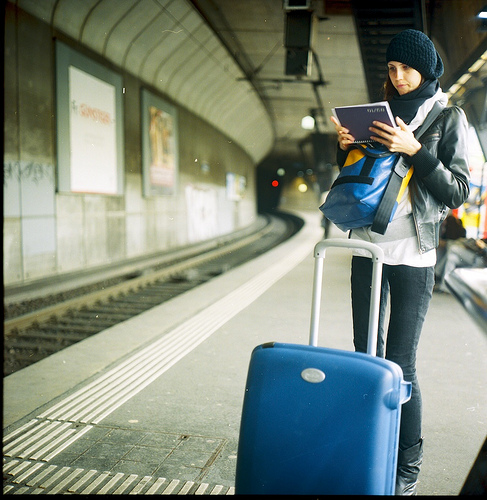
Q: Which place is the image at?
A: It is at the train station.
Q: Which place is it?
A: It is a train station.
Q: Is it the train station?
A: Yes, it is the train station.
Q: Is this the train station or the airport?
A: It is the train station.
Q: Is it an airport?
A: No, it is a train station.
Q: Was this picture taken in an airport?
A: No, the picture was taken in a train station.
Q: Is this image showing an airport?
A: No, the picture is showing a train station.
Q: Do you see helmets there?
A: No, there are no helmets.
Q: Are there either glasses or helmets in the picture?
A: No, there are no helmets or glasses.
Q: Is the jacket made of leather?
A: Yes, the jacket is made of leather.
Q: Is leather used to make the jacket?
A: Yes, the jacket is made of leather.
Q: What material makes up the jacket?
A: The jacket is made of leather.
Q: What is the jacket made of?
A: The jacket is made of leather.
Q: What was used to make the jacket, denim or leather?
A: The jacket is made of leather.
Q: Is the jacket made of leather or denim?
A: The jacket is made of leather.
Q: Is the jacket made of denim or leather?
A: The jacket is made of leather.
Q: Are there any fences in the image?
A: No, there are no fences.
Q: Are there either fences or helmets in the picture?
A: No, there are no fences or helmets.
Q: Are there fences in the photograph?
A: No, there are no fences.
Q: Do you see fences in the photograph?
A: No, there are no fences.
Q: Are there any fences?
A: No, there are no fences.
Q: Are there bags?
A: Yes, there is a bag.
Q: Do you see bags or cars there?
A: Yes, there is a bag.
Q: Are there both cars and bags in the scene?
A: No, there is a bag but no cars.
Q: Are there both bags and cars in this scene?
A: No, there is a bag but no cars.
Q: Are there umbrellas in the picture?
A: No, there are no umbrellas.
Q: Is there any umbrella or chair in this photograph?
A: No, there are no umbrellas or chairs.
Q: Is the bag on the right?
A: Yes, the bag is on the right of the image.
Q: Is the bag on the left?
A: No, the bag is on the right of the image.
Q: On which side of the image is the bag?
A: The bag is on the right of the image.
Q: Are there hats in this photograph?
A: Yes, there is a hat.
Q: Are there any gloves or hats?
A: Yes, there is a hat.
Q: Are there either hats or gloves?
A: Yes, there is a hat.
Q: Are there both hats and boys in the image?
A: No, there is a hat but no boys.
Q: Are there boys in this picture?
A: No, there are no boys.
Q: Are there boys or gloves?
A: No, there are no boys or gloves.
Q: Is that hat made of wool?
A: Yes, the hat is made of wool.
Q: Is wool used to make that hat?
A: Yes, the hat is made of wool.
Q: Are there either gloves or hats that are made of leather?
A: No, there is a hat but it is made of wool.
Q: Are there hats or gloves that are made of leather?
A: No, there is a hat but it is made of wool.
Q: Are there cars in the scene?
A: No, there are no cars.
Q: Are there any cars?
A: No, there are no cars.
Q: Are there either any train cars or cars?
A: No, there are no cars or train cars.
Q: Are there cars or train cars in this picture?
A: No, there are no cars or train cars.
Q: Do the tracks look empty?
A: Yes, the tracks are empty.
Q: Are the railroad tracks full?
A: No, the railroad tracks are empty.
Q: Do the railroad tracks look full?
A: No, the railroad tracks are empty.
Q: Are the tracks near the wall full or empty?
A: The railroad tracks are empty.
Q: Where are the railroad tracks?
A: The railroad tracks are in the train station.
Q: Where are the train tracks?
A: The railroad tracks are in the train station.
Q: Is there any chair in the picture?
A: No, there are no chairs.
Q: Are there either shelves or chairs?
A: No, there are no chairs or shelves.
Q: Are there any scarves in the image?
A: Yes, there is a scarf.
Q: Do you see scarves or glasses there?
A: Yes, there is a scarf.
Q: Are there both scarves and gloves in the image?
A: No, there is a scarf but no gloves.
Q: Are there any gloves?
A: No, there are no gloves.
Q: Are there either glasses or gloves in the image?
A: No, there are no gloves or glasses.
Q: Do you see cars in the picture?
A: No, there are no cars.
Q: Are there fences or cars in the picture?
A: No, there are no cars or fences.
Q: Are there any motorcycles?
A: No, there are no motorcycles.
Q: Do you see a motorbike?
A: No, there are no motorcycles.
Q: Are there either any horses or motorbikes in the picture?
A: No, there are no motorbikes or horses.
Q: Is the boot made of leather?
A: Yes, the boot is made of leather.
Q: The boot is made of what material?
A: The boot is made of leather.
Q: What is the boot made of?
A: The boot is made of leather.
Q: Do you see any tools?
A: No, there are no tools.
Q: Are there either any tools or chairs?
A: No, there are no tools or chairs.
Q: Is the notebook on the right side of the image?
A: Yes, the notebook is on the right of the image.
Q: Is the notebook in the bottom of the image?
A: No, the notebook is in the top of the image.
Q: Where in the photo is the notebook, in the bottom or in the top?
A: The notebook is in the top of the image.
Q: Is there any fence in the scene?
A: No, there are no fences.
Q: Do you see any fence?
A: No, there are no fences.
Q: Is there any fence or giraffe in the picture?
A: No, there are no fences or giraffes.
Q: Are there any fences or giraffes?
A: No, there are no fences or giraffes.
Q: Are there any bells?
A: No, there are no bells.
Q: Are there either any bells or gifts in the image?
A: No, there are no bells or gifts.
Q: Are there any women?
A: Yes, there is a woman.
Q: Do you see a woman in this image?
A: Yes, there is a woman.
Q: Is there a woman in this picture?
A: Yes, there is a woman.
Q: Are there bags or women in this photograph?
A: Yes, there is a woman.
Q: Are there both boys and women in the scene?
A: No, there is a woman but no boys.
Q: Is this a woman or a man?
A: This is a woman.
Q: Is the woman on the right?
A: Yes, the woman is on the right of the image.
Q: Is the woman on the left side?
A: No, the woman is on the right of the image.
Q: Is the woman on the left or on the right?
A: The woman is on the right of the image.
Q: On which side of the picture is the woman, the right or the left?
A: The woman is on the right of the image.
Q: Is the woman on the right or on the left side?
A: The woman is on the right of the image.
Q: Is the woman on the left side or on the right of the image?
A: The woman is on the right of the image.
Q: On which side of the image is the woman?
A: The woman is on the right of the image.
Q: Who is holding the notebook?
A: The woman is holding the notebook.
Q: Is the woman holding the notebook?
A: Yes, the woman is holding the notebook.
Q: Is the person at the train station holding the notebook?
A: Yes, the woman is holding the notebook.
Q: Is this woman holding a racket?
A: No, the woman is holding the notebook.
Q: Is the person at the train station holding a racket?
A: No, the woman is holding the notebook.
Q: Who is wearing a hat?
A: The woman is wearing a hat.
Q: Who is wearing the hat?
A: The woman is wearing a hat.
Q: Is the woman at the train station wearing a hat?
A: Yes, the woman is wearing a hat.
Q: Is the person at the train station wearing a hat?
A: Yes, the woman is wearing a hat.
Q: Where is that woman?
A: The woman is at the train station.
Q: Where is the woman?
A: The woman is at the train station.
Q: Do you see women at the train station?
A: Yes, there is a woman at the train station.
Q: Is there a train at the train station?
A: No, there is a woman at the train station.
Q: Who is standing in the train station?
A: The woman is standing in the train station.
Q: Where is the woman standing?
A: The woman is standing in the train station.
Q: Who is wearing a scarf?
A: The woman is wearing a scarf.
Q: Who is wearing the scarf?
A: The woman is wearing a scarf.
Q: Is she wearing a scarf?
A: Yes, the woman is wearing a scarf.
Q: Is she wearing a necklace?
A: No, the woman is wearing a scarf.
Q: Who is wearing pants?
A: The woman is wearing pants.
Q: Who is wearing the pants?
A: The woman is wearing pants.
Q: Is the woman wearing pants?
A: Yes, the woman is wearing pants.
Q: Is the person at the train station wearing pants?
A: Yes, the woman is wearing pants.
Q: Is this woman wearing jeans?
A: No, the woman is wearing pants.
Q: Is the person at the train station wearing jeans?
A: No, the woman is wearing pants.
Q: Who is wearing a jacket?
A: The woman is wearing a jacket.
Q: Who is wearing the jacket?
A: The woman is wearing a jacket.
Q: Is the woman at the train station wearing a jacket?
A: Yes, the woman is wearing a jacket.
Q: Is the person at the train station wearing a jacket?
A: Yes, the woman is wearing a jacket.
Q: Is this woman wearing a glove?
A: No, the woman is wearing a jacket.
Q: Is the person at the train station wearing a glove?
A: No, the woman is wearing a jacket.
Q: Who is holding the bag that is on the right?
A: The woman is holding the bag.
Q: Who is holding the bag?
A: The woman is holding the bag.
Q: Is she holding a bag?
A: Yes, the woman is holding a bag.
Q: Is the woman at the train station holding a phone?
A: No, the woman is holding a bag.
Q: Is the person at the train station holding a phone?
A: No, the woman is holding a bag.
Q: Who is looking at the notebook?
A: The woman is looking at the notebook.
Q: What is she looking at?
A: The woman is looking at the notebook.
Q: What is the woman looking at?
A: The woman is looking at the notebook.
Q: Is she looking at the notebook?
A: Yes, the woman is looking at the notebook.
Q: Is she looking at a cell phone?
A: No, the woman is looking at the notebook.